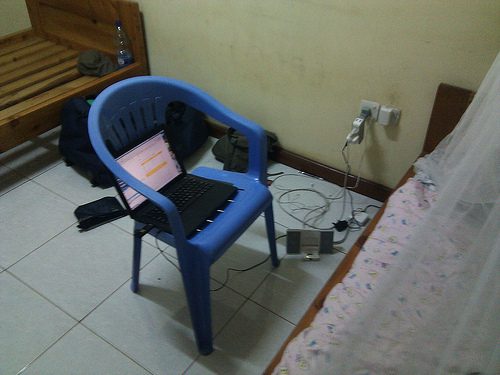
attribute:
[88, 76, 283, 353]
chair — plastic, blue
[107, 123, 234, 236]
laptop — black, open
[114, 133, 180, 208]
screen — glowing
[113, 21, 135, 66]
bottle — plastic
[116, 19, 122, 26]
bottle cap — blue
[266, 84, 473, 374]
frame of bed — brown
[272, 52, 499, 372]
tulle — white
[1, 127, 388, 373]
floor — white, tiled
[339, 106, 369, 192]
plugs — electrical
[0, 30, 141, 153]
bench — wooden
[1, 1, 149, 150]
frame of bed — mattressless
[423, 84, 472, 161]
headboard — wooden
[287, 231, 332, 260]
stereo — small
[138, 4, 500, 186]
wall — beige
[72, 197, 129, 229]
object — black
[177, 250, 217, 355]
leg of chair — blue